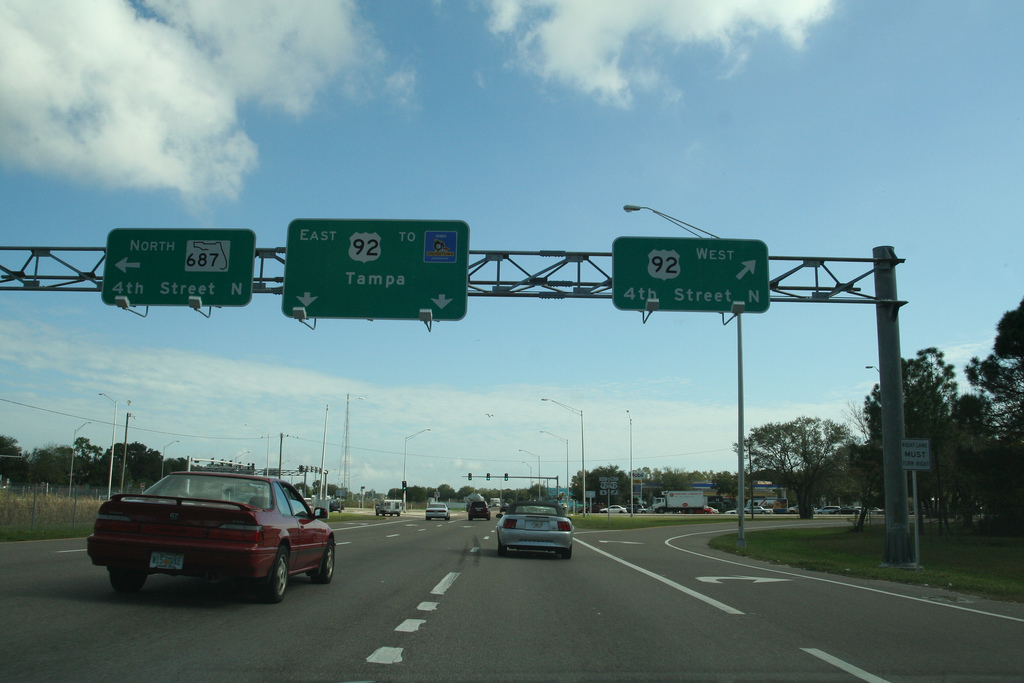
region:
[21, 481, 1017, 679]
A multi lane highway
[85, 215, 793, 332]
large green and white street signs hang over the road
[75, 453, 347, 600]
A red car driving on the road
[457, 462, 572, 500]
A trafic light in the distance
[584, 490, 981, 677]
A turn lane to the right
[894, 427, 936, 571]
A black and white street sign on a pole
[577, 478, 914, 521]
Vehicles stopped at a traffic light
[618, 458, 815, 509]
A gas station by the intersection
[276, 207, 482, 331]
The middle sign gives direction to Tampa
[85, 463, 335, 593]
red car on the street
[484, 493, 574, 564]
silver car on the street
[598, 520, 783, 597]
white arrows painted on the street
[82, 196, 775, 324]
green street signs over the street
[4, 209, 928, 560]
pole and structure green signs are attached to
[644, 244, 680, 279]
black number on white background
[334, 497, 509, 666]
white dashed lines on the street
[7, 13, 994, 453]
blue sky with white clouds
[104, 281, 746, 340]
lights attached to green signs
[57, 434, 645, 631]
Two cars driving towards US 92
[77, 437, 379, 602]
Red car driving towards US highway 92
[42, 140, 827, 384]
three traffic direction signs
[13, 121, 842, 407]
traffic control signs for roadway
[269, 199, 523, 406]
Traffic direction for US 92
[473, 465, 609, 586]
Silver convertible Ford Mustang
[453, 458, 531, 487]
three traffic control signals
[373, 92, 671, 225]
a view of sky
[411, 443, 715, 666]
a car in road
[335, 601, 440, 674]
lines in the road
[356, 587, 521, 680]
a view of lines in road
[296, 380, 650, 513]
a view of clouds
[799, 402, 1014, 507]
a view of trees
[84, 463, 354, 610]
red car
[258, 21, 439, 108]
white clouds in blue sky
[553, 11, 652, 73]
white clouds in blue sky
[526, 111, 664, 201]
white clouds in blue sky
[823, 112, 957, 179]
white clouds in blue sky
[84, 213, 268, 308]
green and white sign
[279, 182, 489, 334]
green and white sign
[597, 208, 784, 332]
green and white sign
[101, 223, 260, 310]
green sign with white letters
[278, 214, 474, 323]
green sign with white letters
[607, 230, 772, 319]
green sign with white letters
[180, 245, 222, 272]
black numbers on white background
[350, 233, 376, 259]
black numbers on white background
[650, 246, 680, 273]
black numbers on white background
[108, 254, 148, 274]
white directional arrow on green sign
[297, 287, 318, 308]
white directional arrow on green sign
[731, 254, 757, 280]
white directional arrow on green sign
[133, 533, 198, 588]
A white rectangular license plate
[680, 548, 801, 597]
White arrow on the street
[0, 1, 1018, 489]
White clouds in a blue sky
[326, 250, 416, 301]
"Tampa" written on the sign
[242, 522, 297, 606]
A black car tire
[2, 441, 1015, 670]
Many cars driving on the street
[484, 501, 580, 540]
Two read rear car lights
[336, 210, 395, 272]
Number 92 on a sign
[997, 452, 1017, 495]
green leaves on the tree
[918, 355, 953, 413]
green leaves on the tree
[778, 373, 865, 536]
green leaves on the tree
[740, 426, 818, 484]
green leaves on the tree